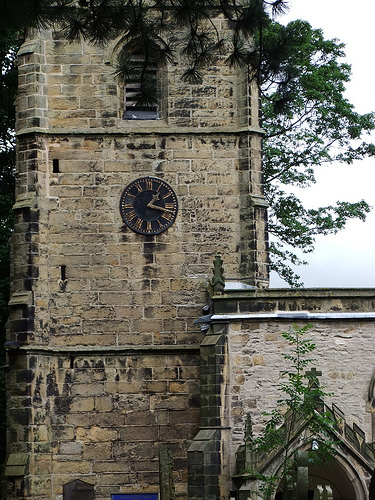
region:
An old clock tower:
[7, 0, 273, 499]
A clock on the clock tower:
[119, 176, 176, 235]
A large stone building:
[186, 255, 369, 497]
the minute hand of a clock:
[147, 202, 175, 214]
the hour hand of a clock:
[148, 190, 160, 205]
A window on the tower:
[115, 44, 164, 122]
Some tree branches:
[4, 1, 374, 287]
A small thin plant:
[239, 319, 344, 497]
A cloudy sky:
[1, 2, 374, 291]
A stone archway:
[235, 370, 373, 499]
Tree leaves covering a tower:
[57, 5, 236, 26]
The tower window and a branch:
[127, 85, 158, 113]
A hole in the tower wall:
[60, 263, 65, 279]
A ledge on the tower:
[90, 346, 129, 351]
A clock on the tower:
[130, 184, 168, 226]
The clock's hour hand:
[151, 193, 159, 199]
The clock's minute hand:
[153, 206, 163, 210]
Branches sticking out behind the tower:
[262, 32, 281, 58]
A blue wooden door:
[115, 495, 155, 498]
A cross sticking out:
[306, 366, 320, 374]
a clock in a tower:
[113, 170, 182, 242]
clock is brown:
[115, 172, 187, 247]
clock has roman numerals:
[112, 168, 180, 245]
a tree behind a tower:
[3, 1, 373, 257]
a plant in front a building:
[186, 285, 366, 498]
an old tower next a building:
[5, 10, 372, 496]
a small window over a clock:
[101, 24, 187, 134]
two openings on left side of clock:
[49, 149, 75, 292]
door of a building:
[238, 387, 373, 498]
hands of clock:
[138, 187, 178, 219]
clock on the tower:
[109, 169, 195, 240]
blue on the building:
[105, 485, 157, 496]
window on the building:
[112, 33, 167, 129]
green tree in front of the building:
[278, 319, 335, 453]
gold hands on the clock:
[146, 189, 178, 215]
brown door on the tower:
[58, 472, 96, 498]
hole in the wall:
[50, 155, 60, 175]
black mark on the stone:
[74, 361, 120, 383]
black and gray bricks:
[196, 347, 223, 410]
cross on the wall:
[301, 362, 322, 388]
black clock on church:
[120, 176, 178, 235]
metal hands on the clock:
[146, 191, 172, 213]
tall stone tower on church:
[4, 1, 269, 499]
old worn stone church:
[4, 0, 374, 499]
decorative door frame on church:
[232, 366, 373, 498]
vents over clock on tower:
[122, 42, 158, 119]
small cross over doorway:
[304, 367, 322, 384]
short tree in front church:
[237, 318, 340, 498]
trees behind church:
[0, 0, 374, 324]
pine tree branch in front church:
[0, 0, 300, 115]